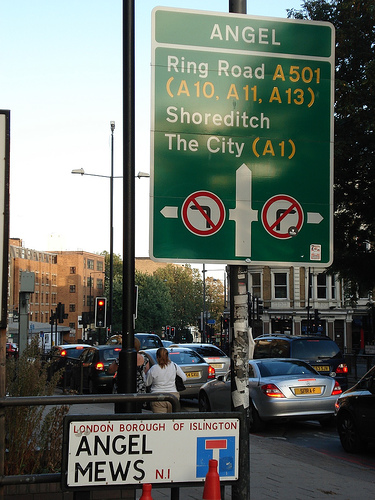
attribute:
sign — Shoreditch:
[148, 4, 338, 270]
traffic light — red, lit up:
[89, 293, 117, 329]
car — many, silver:
[196, 356, 343, 433]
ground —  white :
[299, 153, 322, 176]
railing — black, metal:
[94, 388, 185, 408]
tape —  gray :
[227, 293, 254, 411]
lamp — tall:
[69, 120, 148, 342]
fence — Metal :
[1, 386, 253, 499]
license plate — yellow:
[291, 384, 324, 394]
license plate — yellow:
[312, 362, 329, 371]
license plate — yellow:
[182, 368, 204, 379]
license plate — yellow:
[210, 360, 224, 370]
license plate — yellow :
[294, 385, 325, 395]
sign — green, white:
[134, 5, 320, 251]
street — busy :
[177, 391, 335, 495]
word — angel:
[202, 20, 281, 63]